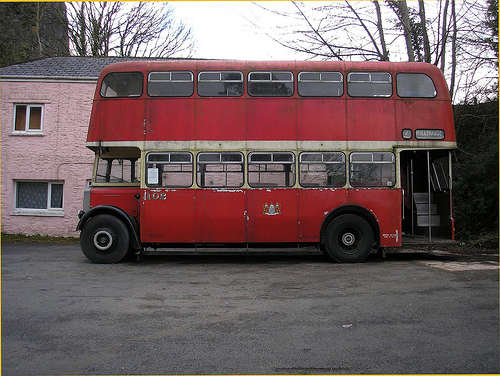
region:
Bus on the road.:
[63, 50, 466, 264]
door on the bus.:
[398, 148, 457, 246]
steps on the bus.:
[410, 178, 447, 241]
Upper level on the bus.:
[81, 53, 463, 148]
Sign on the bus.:
[139, 162, 164, 187]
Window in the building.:
[7, 172, 67, 219]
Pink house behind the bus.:
[0, 49, 340, 245]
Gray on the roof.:
[1, 50, 238, 84]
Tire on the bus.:
[77, 210, 133, 267]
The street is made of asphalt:
[54, 280, 464, 363]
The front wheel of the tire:
[68, 205, 135, 265]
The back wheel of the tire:
[318, 203, 379, 267]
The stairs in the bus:
[410, 181, 445, 234]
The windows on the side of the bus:
[99, 61, 441, 109]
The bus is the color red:
[139, 103, 409, 140]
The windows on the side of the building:
[5, 88, 77, 228]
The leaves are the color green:
[459, 100, 497, 232]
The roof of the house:
[2, 53, 102, 86]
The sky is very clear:
[189, 3, 285, 56]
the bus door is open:
[396, 148, 450, 239]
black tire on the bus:
[78, 214, 127, 265]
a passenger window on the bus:
[144, 150, 194, 186]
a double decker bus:
[83, 58, 456, 263]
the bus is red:
[80, 60, 457, 252]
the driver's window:
[93, 157, 140, 186]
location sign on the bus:
[413, 127, 445, 142]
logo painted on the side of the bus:
[261, 199, 283, 218]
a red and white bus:
[53, 54, 466, 283]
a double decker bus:
[61, 52, 468, 297]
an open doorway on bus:
[364, 136, 466, 258]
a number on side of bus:
[138, 183, 184, 206]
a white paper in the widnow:
[142, 158, 179, 189]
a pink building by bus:
[12, 45, 452, 270]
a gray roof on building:
[5, 44, 404, 94]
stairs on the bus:
[406, 182, 444, 235]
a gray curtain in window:
[13, 174, 74, 215]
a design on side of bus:
[243, 192, 314, 229]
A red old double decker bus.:
[56, 54, 479, 282]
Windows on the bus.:
[147, 152, 397, 202]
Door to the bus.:
[397, 167, 462, 242]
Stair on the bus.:
[413, 174, 440, 231]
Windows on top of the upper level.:
[142, 64, 429, 109]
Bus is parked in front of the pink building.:
[21, 47, 447, 267]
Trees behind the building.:
[37, 9, 199, 65]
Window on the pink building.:
[7, 94, 54, 141]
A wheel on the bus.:
[80, 210, 130, 265]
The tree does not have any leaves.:
[300, 4, 461, 54]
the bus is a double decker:
[76, 60, 458, 260]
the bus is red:
[75, 56, 456, 261]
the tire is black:
[80, 212, 131, 263]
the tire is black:
[326, 214, 375, 260]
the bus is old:
[76, 58, 458, 260]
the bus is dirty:
[75, 59, 457, 265]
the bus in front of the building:
[1, 55, 457, 263]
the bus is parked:
[74, 58, 460, 260]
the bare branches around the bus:
[1, 0, 498, 262]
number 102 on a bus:
[143, 190, 173, 202]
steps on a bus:
[407, 185, 442, 232]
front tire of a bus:
[73, 208, 136, 265]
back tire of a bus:
[321, 206, 383, 261]